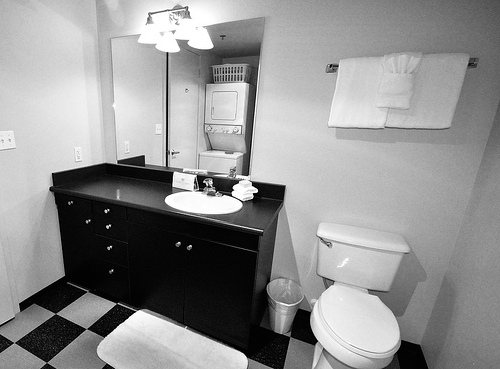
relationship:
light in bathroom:
[137, 5, 215, 54] [0, 0, 499, 368]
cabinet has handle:
[132, 227, 256, 352] [185, 244, 195, 256]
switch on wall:
[0, 130, 17, 154] [3, 1, 105, 307]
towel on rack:
[326, 58, 389, 137] [326, 53, 484, 73]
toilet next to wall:
[311, 218, 414, 366] [97, 1, 496, 354]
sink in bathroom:
[166, 189, 243, 220] [0, 0, 499, 368]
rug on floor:
[99, 306, 249, 368] [3, 276, 427, 367]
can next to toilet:
[261, 274, 304, 335] [311, 218, 414, 366]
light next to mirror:
[137, 5, 215, 54] [108, 14, 268, 178]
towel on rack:
[385, 49, 469, 131] [326, 53, 484, 73]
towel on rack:
[379, 49, 423, 111] [326, 53, 484, 73]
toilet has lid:
[311, 218, 414, 366] [319, 283, 400, 355]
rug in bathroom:
[99, 306, 249, 368] [0, 0, 499, 368]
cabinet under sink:
[132, 227, 256, 352] [166, 189, 243, 220]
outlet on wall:
[73, 144, 85, 165] [3, 1, 105, 307]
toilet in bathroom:
[311, 218, 414, 366] [0, 0, 499, 368]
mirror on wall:
[108, 14, 268, 178] [97, 1, 496, 354]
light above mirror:
[137, 5, 215, 54] [108, 14, 268, 178]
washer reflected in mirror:
[198, 153, 247, 179] [108, 14, 268, 178]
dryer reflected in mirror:
[202, 85, 250, 139] [108, 14, 268, 178]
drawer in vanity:
[90, 200, 126, 220] [49, 159, 285, 351]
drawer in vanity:
[92, 217, 130, 242] [49, 159, 285, 351]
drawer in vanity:
[94, 229, 131, 267] [49, 159, 285, 351]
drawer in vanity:
[94, 256, 132, 299] [49, 159, 285, 351]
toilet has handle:
[311, 218, 414, 366] [317, 231, 333, 249]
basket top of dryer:
[208, 58, 253, 83] [202, 85, 250, 139]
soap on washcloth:
[238, 177, 252, 188] [231, 183, 258, 195]